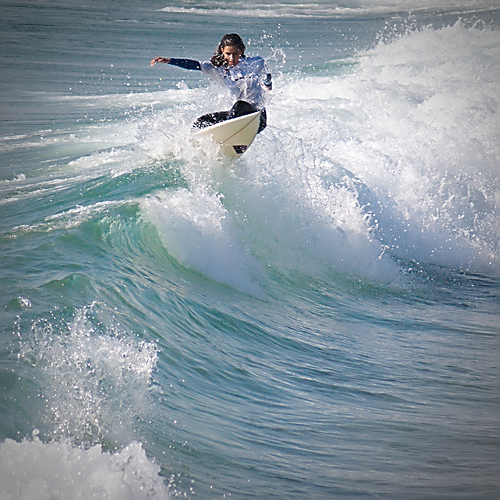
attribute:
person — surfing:
[151, 26, 282, 124]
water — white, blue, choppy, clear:
[4, 5, 494, 497]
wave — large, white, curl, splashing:
[166, 7, 497, 285]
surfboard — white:
[187, 107, 268, 175]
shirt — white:
[201, 55, 276, 106]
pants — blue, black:
[190, 97, 271, 132]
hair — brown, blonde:
[205, 32, 245, 66]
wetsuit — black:
[168, 56, 282, 154]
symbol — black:
[231, 143, 250, 159]